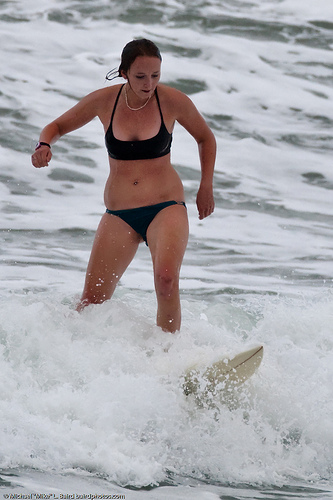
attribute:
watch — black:
[32, 138, 53, 149]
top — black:
[104, 83, 172, 161]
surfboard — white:
[133, 339, 294, 423]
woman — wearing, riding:
[31, 34, 216, 334]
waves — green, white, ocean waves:
[3, 2, 328, 493]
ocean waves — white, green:
[207, 10, 327, 150]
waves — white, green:
[224, 31, 270, 102]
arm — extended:
[30, 83, 108, 160]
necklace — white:
[124, 102, 144, 115]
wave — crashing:
[31, 372, 129, 449]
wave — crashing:
[243, 320, 332, 392]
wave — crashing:
[0, 400, 325, 487]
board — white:
[180, 343, 267, 401]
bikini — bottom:
[95, 199, 190, 240]